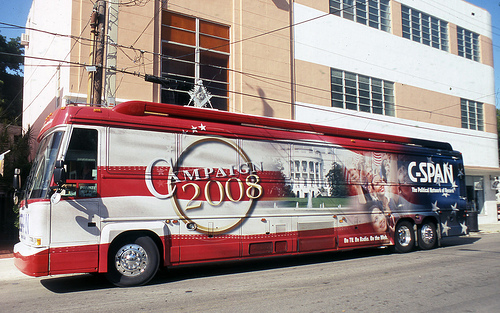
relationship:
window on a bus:
[64, 133, 107, 202] [30, 76, 480, 270]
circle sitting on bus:
[152, 132, 278, 235] [31, 64, 484, 258]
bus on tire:
[12, 97, 477, 288] [413, 221, 437, 249]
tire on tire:
[413, 221, 437, 249] [393, 219, 417, 254]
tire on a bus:
[100, 227, 172, 284] [19, 41, 469, 268]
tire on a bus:
[394, 219, 416, 253] [12, 97, 477, 288]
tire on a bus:
[416, 225, 438, 249] [12, 97, 477, 288]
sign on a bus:
[116, 126, 308, 231] [12, 97, 477, 288]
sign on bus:
[408, 160, 453, 193] [12, 97, 477, 288]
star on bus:
[429, 199, 441, 214] [22, 109, 467, 273]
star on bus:
[429, 199, 441, 214] [12, 97, 477, 288]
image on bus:
[278, 144, 355, 208] [12, 97, 477, 288]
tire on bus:
[101, 230, 161, 288] [12, 97, 477, 288]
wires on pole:
[3, 12, 495, 171] [85, 0, 107, 108]